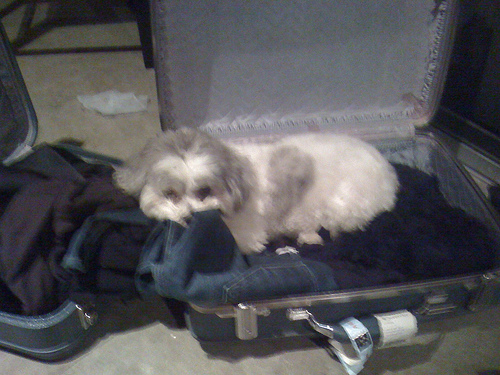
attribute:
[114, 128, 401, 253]
dog — little, gray, white, resting, looking at camera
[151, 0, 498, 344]
suitcase — open, large, blue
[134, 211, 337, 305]
blue jeans — folded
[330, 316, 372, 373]
tag — white, luggage tag, blue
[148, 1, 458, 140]
top — white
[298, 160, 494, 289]
clothing — dark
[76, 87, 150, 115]
tissue — white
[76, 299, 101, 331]
clasp — silver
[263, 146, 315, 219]
spot — gray